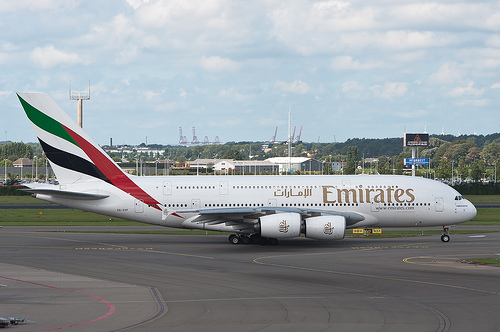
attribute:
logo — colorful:
[17, 89, 191, 224]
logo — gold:
[271, 185, 415, 203]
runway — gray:
[2, 224, 498, 330]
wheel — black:
[440, 235, 450, 245]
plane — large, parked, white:
[17, 90, 478, 243]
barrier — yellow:
[353, 227, 367, 235]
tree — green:
[481, 139, 500, 184]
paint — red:
[0, 272, 115, 331]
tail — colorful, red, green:
[16, 89, 124, 219]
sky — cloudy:
[0, 1, 499, 147]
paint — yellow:
[403, 250, 464, 272]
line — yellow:
[254, 242, 500, 319]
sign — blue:
[404, 157, 431, 166]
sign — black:
[403, 134, 432, 148]